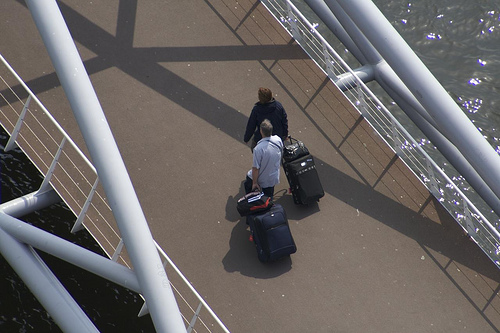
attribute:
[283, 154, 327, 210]
suitcase — black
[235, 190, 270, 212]
tote bag — red, black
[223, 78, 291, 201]
men — walking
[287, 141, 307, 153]
purse — black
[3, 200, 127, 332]
poles — white